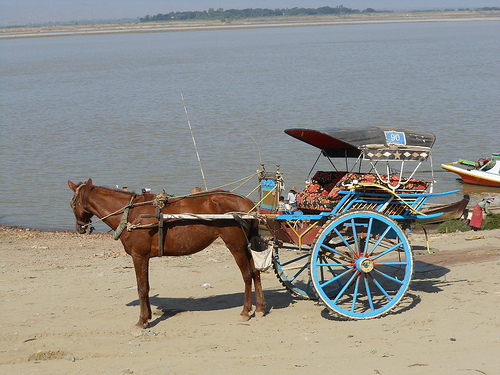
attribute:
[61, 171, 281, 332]
horse — brown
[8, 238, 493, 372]
road — brown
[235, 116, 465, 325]
cart — large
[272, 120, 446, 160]
cart cover — black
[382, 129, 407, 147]
number — 90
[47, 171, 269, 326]
horse — brown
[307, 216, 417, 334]
wheel — blue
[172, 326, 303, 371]
ground — dusty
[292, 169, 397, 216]
seat — floral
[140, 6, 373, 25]
trees — sandy, blue